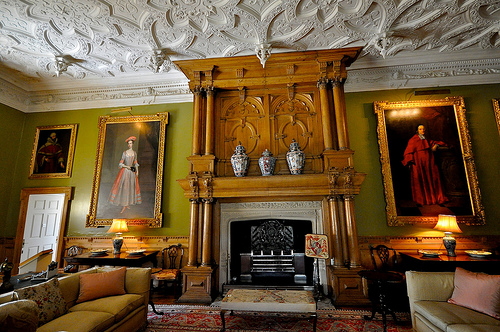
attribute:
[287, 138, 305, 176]
vase — largest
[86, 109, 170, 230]
painting — large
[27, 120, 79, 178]
painting — small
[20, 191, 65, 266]
door — white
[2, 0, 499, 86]
ceiling — white, designed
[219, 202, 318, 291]
fireplace — large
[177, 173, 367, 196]
mantle — brown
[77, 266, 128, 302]
pillow — decorative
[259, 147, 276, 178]
vase — grey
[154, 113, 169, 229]
frame — gold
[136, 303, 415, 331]
rug — red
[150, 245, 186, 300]
chair — wooden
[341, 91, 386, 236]
wall — green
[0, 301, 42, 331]
pillow — obscured